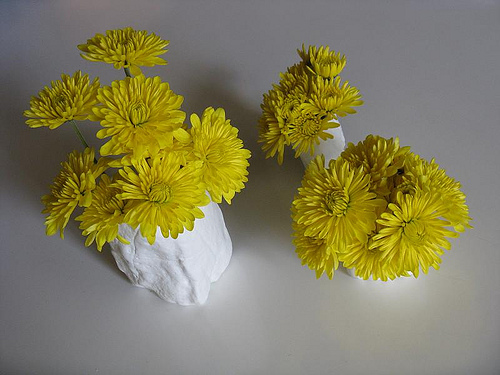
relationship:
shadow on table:
[5, 119, 43, 209] [4, 9, 85, 361]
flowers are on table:
[24, 24, 472, 307] [4, 9, 85, 361]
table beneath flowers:
[4, 9, 85, 361] [24, 24, 472, 307]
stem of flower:
[71, 123, 92, 151] [24, 67, 98, 150]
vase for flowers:
[103, 213, 258, 317] [24, 24, 472, 307]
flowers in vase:
[24, 24, 472, 307] [103, 213, 258, 317]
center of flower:
[148, 178, 176, 204] [120, 154, 213, 243]